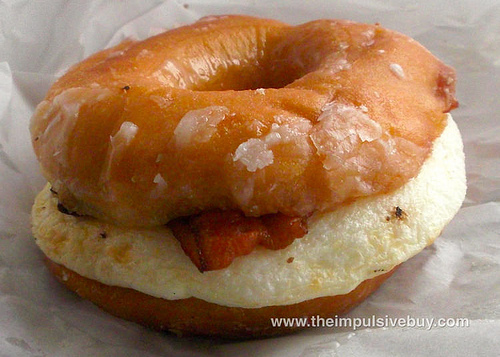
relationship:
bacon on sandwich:
[166, 207, 309, 274] [28, 13, 467, 340]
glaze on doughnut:
[224, 101, 427, 217] [31, 28, 466, 337]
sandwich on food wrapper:
[97, 74, 331, 324] [0, 0, 499, 356]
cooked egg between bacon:
[30, 111, 467, 310] [166, 232, 274, 265]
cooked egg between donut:
[30, 111, 467, 310] [28, 14, 459, 229]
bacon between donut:
[166, 232, 274, 265] [28, 14, 459, 229]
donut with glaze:
[28, 12, 456, 208] [237, 102, 380, 175]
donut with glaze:
[47, 267, 390, 333] [35, 87, 115, 167]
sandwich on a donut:
[28, 13, 467, 340] [30, 13, 468, 339]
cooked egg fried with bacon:
[30, 111, 467, 310] [173, 209, 313, 276]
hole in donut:
[183, 49, 318, 97] [25, 9, 462, 234]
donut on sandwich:
[28, 14, 459, 229] [21, 36, 470, 330]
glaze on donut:
[223, 130, 293, 171] [112, 58, 186, 84]